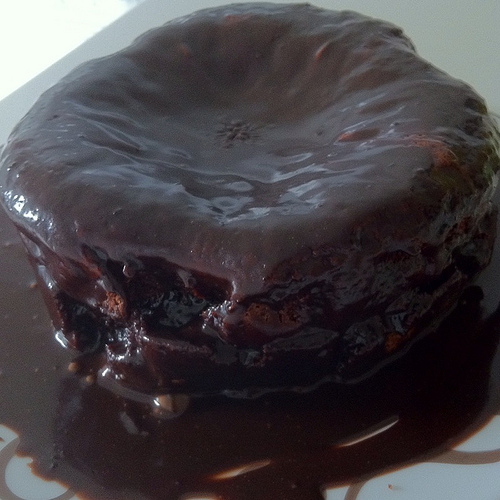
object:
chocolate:
[65, 140, 399, 480]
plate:
[23, 420, 411, 477]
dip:
[61, 236, 224, 386]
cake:
[0, 13, 461, 444]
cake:
[18, 121, 429, 454]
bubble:
[131, 369, 203, 411]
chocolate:
[57, 115, 410, 336]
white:
[24, 6, 88, 60]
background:
[32, 6, 182, 36]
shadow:
[84, 25, 151, 84]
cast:
[97, 16, 269, 66]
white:
[300, 406, 415, 464]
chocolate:
[185, 304, 453, 428]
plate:
[224, 420, 407, 469]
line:
[331, 405, 481, 498]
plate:
[197, 360, 451, 478]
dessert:
[8, 5, 462, 467]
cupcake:
[49, 49, 485, 440]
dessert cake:
[26, 30, 435, 460]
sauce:
[108, 308, 279, 484]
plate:
[180, 368, 440, 493]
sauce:
[31, 414, 402, 498]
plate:
[183, 380, 452, 483]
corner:
[401, 439, 497, 495]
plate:
[187, 389, 438, 493]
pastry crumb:
[52, 289, 248, 360]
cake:
[66, 106, 386, 427]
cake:
[21, 68, 494, 440]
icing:
[165, 87, 302, 179]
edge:
[0, 10, 60, 95]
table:
[0, 4, 86, 180]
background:
[22, 12, 93, 53]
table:
[1, 6, 98, 116]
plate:
[250, 417, 417, 480]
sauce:
[191, 344, 443, 496]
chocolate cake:
[287, 198, 362, 466]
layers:
[290, 246, 327, 464]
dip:
[187, 80, 303, 191]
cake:
[0, 0, 446, 485]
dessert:
[22, 17, 490, 493]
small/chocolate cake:
[0, 1, 484, 389]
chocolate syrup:
[3, 235, 482, 496]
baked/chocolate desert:
[3, 1, 482, 416]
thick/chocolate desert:
[7, 3, 482, 415]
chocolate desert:
[4, 5, 484, 424]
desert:
[7, 1, 471, 418]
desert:
[9, 2, 480, 497]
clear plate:
[400, 473, 465, 498]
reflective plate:
[14, 401, 114, 496]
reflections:
[48, 380, 315, 498]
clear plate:
[3, 417, 483, 492]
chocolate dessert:
[8, 5, 483, 389]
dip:
[174, 52, 314, 172]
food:
[4, 0, 484, 424]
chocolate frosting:
[6, 6, 484, 295]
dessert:
[5, 4, 480, 417]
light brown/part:
[104, 292, 124, 313]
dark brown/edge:
[213, 277, 403, 347]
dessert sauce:
[37, 392, 269, 466]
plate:
[2, 388, 462, 496]